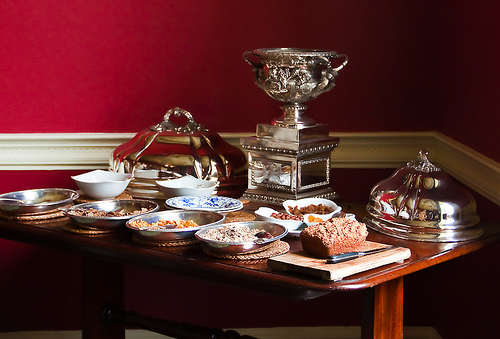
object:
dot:
[248, 154, 298, 194]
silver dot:
[242, 189, 285, 206]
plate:
[63, 199, 160, 230]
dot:
[259, 146, 262, 151]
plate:
[193, 221, 289, 261]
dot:
[253, 146, 257, 150]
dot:
[295, 150, 299, 154]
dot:
[315, 146, 317, 151]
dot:
[335, 142, 338, 147]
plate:
[125, 208, 225, 242]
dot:
[301, 149, 304, 153]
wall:
[0, 0, 500, 135]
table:
[0, 177, 500, 339]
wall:
[0, 0, 499, 164]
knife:
[326, 247, 391, 264]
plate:
[0, 187, 80, 218]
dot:
[295, 149, 304, 155]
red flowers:
[164, 195, 245, 214]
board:
[265, 240, 411, 283]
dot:
[334, 192, 336, 195]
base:
[236, 188, 342, 211]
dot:
[289, 149, 293, 153]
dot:
[241, 144, 245, 148]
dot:
[271, 148, 274, 152]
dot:
[309, 147, 313, 152]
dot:
[330, 144, 333, 147]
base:
[236, 135, 340, 214]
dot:
[314, 146, 317, 151]